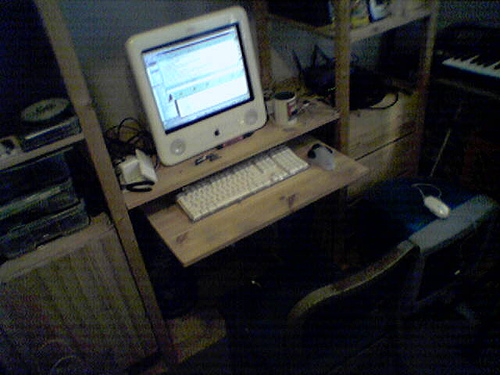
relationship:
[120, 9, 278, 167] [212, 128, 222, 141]
computer made by apple